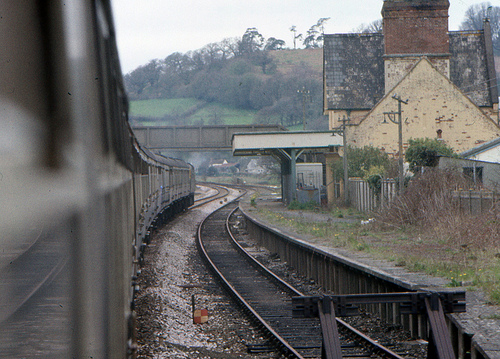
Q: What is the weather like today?
A: It is overcast.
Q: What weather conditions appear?
A: It is overcast.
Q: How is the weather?
A: It is overcast.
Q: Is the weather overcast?
A: Yes, it is overcast.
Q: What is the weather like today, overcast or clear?
A: It is overcast.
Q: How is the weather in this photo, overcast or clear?
A: It is overcast.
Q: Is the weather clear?
A: No, it is overcast.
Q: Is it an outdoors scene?
A: Yes, it is outdoors.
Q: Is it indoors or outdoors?
A: It is outdoors.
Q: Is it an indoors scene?
A: No, it is outdoors.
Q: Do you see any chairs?
A: No, there are no chairs.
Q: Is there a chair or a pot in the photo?
A: No, there are no chairs or pots.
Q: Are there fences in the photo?
A: Yes, there is a fence.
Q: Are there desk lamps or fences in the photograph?
A: Yes, there is a fence.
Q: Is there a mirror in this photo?
A: No, there are no mirrors.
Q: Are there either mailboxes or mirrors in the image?
A: No, there are no mirrors or mailboxes.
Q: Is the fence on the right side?
A: Yes, the fence is on the right of the image.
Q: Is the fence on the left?
A: No, the fence is on the right of the image.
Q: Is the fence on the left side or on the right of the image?
A: The fence is on the right of the image.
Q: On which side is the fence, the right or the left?
A: The fence is on the right of the image.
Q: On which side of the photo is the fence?
A: The fence is on the right of the image.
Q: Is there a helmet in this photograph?
A: No, there are no helmets.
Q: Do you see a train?
A: Yes, there is a train.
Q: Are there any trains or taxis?
A: Yes, there is a train.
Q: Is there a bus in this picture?
A: No, there are no buses.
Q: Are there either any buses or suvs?
A: No, there are no buses or suvs.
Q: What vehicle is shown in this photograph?
A: The vehicle is a train.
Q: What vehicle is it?
A: The vehicle is a train.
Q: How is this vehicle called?
A: This is a train.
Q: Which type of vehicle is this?
A: This is a train.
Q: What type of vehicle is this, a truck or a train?
A: This is a train.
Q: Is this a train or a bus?
A: This is a train.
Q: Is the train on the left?
A: Yes, the train is on the left of the image.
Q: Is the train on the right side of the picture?
A: No, the train is on the left of the image.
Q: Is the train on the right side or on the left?
A: The train is on the left of the image.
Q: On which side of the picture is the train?
A: The train is on the left of the image.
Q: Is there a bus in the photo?
A: No, there are no buses.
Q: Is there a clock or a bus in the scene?
A: No, there are no buses or clocks.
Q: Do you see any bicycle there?
A: No, there are no bicycles.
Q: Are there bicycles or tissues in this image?
A: No, there are no bicycles or tissues.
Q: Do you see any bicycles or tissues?
A: No, there are no bicycles or tissues.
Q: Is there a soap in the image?
A: No, there are no soaps.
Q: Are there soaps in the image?
A: No, there are no soaps.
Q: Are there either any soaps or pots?
A: No, there are no soaps or pots.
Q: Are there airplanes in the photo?
A: No, there are no airplanes.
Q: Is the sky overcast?
A: Yes, the sky is overcast.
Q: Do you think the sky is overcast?
A: Yes, the sky is overcast.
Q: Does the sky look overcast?
A: Yes, the sky is overcast.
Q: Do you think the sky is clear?
A: No, the sky is overcast.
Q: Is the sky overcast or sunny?
A: The sky is overcast.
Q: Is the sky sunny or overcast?
A: The sky is overcast.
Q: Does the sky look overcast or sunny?
A: The sky is overcast.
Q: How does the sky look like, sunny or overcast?
A: The sky is overcast.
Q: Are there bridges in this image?
A: Yes, there is a bridge.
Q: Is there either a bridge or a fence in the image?
A: Yes, there is a bridge.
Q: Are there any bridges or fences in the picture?
A: Yes, there is a bridge.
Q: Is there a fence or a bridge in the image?
A: Yes, there is a bridge.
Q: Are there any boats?
A: No, there are no boats.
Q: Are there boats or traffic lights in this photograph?
A: No, there are no boats or traffic lights.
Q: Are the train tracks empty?
A: Yes, the train tracks are empty.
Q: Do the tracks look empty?
A: Yes, the tracks are empty.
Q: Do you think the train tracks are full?
A: No, the train tracks are empty.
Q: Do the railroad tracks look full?
A: No, the railroad tracks are empty.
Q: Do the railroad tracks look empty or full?
A: The railroad tracks are empty.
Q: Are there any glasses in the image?
A: No, there are no glasses.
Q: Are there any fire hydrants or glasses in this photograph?
A: No, there are no glasses or fire hydrants.